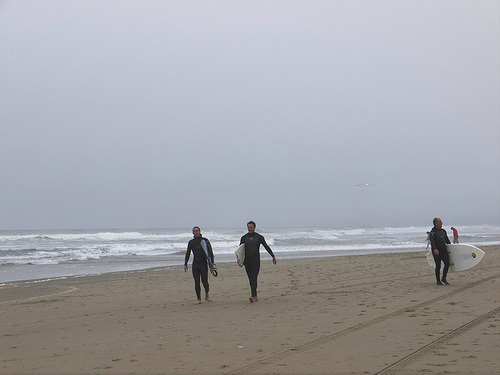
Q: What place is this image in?
A: It is at the beach.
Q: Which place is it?
A: It is a beach.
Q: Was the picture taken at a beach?
A: Yes, it was taken in a beach.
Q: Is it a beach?
A: Yes, it is a beach.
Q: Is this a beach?
A: Yes, it is a beach.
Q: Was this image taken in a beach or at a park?
A: It was taken at a beach.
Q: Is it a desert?
A: No, it is a beach.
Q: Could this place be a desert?
A: No, it is a beach.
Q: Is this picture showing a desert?
A: No, the picture is showing a beach.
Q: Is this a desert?
A: No, it is a beach.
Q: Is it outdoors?
A: Yes, it is outdoors.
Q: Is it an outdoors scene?
A: Yes, it is outdoors.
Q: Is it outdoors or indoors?
A: It is outdoors.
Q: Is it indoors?
A: No, it is outdoors.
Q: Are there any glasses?
A: No, there are no glasses.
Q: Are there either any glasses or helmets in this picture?
A: No, there are no glasses or helmets.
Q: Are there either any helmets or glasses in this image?
A: No, there are no glasses or helmets.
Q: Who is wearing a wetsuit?
A: The man is wearing a wetsuit.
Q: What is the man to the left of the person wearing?
A: The man is wearing a wetsuit.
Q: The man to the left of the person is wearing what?
A: The man is wearing a wetsuit.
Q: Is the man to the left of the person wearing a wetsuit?
A: Yes, the man is wearing a wetsuit.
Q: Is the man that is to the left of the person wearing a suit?
A: No, the man is wearing a wetsuit.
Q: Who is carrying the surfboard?
A: The man is carrying the surfboard.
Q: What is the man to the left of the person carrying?
A: The man is carrying a surfboard.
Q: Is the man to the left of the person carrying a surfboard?
A: Yes, the man is carrying a surfboard.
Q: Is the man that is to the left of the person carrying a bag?
A: No, the man is carrying a surfboard.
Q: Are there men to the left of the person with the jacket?
A: Yes, there is a man to the left of the person.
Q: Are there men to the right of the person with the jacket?
A: No, the man is to the left of the person.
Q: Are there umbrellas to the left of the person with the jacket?
A: No, there is a man to the left of the person.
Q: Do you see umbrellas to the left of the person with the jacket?
A: No, there is a man to the left of the person.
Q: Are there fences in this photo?
A: No, there are no fences.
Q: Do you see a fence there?
A: No, there are no fences.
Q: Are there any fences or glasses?
A: No, there are no fences or glasses.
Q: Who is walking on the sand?
A: The man is walking on the sand.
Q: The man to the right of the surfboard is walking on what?
A: The man is walking on the sand.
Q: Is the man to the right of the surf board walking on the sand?
A: Yes, the man is walking on the sand.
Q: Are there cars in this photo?
A: No, there are no cars.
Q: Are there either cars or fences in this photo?
A: No, there are no cars or fences.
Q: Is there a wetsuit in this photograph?
A: Yes, there is a wetsuit.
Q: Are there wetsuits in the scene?
A: Yes, there is a wetsuit.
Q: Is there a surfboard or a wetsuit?
A: Yes, there is a wetsuit.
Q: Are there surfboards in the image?
A: Yes, there is a surfboard.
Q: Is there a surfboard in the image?
A: Yes, there is a surfboard.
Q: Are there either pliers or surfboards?
A: Yes, there is a surfboard.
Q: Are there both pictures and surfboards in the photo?
A: No, there is a surfboard but no pictures.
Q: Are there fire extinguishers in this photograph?
A: No, there are no fire extinguishers.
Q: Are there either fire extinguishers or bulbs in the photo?
A: No, there are no fire extinguishers or bulbs.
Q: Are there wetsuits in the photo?
A: Yes, there is a wetsuit.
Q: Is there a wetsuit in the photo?
A: Yes, there is a wetsuit.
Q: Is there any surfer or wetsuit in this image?
A: Yes, there is a wetsuit.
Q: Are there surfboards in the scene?
A: Yes, there is a surfboard.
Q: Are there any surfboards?
A: Yes, there is a surfboard.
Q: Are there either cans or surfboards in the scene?
A: Yes, there is a surfboard.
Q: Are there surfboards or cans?
A: Yes, there is a surfboard.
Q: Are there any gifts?
A: No, there are no gifts.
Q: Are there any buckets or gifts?
A: No, there are no gifts or buckets.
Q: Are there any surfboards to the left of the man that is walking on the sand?
A: Yes, there is a surfboard to the left of the man.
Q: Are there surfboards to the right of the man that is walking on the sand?
A: No, the surfboard is to the left of the man.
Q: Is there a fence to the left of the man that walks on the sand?
A: No, there is a surfboard to the left of the man.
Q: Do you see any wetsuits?
A: Yes, there is a wetsuit.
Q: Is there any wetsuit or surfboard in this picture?
A: Yes, there is a wetsuit.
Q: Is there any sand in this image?
A: Yes, there is sand.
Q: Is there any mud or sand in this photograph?
A: Yes, there is sand.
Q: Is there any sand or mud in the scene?
A: Yes, there is sand.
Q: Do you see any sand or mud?
A: Yes, there is sand.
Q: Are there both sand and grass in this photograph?
A: No, there is sand but no grass.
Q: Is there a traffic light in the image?
A: No, there are no traffic lights.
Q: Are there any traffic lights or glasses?
A: No, there are no traffic lights or glasses.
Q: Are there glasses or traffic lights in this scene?
A: No, there are no traffic lights or glasses.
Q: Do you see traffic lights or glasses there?
A: No, there are no traffic lights or glasses.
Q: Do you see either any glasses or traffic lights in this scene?
A: No, there are no traffic lights or glasses.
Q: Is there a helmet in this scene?
A: No, there are no helmets.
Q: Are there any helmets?
A: No, there are no helmets.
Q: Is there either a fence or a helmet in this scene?
A: No, there are no helmets or fences.